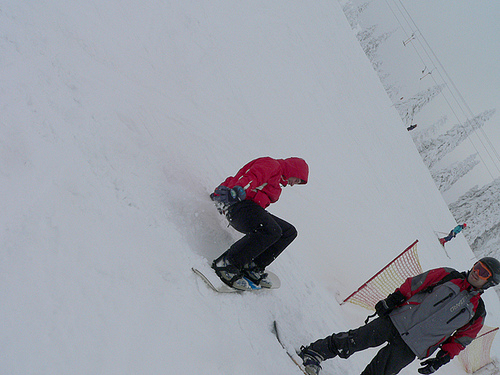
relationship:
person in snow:
[209, 155, 312, 292] [2, 2, 498, 375]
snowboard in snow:
[189, 260, 284, 298] [2, 2, 498, 375]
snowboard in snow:
[270, 318, 308, 373] [2, 2, 498, 375]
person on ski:
[440, 223, 470, 250] [430, 226, 457, 259]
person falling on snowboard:
[209, 155, 312, 292] [189, 260, 284, 298]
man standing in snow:
[296, 254, 499, 373] [2, 2, 498, 375]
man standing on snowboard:
[296, 254, 499, 373] [270, 318, 308, 373]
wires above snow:
[352, 3, 500, 184] [2, 2, 498, 375]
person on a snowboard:
[209, 155, 312, 292] [189, 260, 284, 298]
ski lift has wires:
[398, 28, 420, 52] [352, 3, 500, 184]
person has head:
[209, 155, 312, 292] [277, 148, 311, 190]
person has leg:
[209, 155, 312, 292] [225, 199, 284, 274]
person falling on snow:
[209, 155, 312, 292] [2, 2, 498, 375]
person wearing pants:
[209, 155, 312, 292] [224, 197, 300, 274]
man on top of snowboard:
[296, 254, 499, 373] [270, 318, 308, 373]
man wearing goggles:
[296, 254, 499, 373] [472, 260, 491, 283]